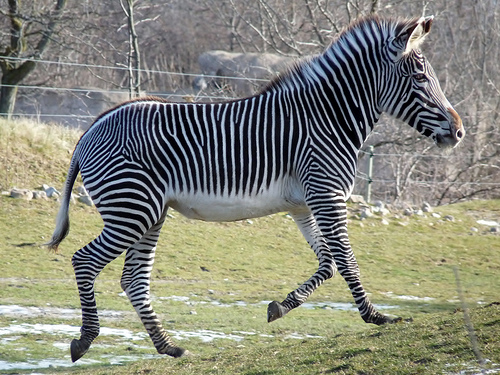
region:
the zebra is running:
[25, 31, 499, 371]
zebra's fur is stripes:
[14, 4, 464, 374]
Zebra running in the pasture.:
[50, 17, 465, 357]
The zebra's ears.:
[400, 15, 435, 53]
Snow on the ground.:
[186, 326, 257, 343]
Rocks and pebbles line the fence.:
[356, 190, 436, 227]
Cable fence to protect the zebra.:
[367, 149, 499, 199]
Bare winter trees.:
[2, 1, 62, 114]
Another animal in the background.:
[199, 49, 284, 89]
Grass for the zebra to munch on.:
[334, 338, 434, 374]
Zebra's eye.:
[411, 68, 432, 85]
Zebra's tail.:
[48, 163, 73, 251]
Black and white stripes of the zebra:
[163, 107, 260, 146]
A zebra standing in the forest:
[23, 0, 473, 372]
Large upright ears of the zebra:
[388, 16, 443, 42]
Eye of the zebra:
[411, 63, 433, 90]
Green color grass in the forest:
[185, 245, 257, 287]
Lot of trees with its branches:
[18, 0, 335, 34]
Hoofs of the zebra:
[64, 341, 202, 361]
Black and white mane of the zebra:
[259, 10, 372, 63]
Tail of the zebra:
[49, 167, 69, 259]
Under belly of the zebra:
[173, 202, 299, 221]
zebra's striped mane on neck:
[270, 18, 394, 85]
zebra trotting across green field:
[41, 11, 468, 361]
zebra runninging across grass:
[40, 10, 467, 362]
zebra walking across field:
[37, 17, 477, 355]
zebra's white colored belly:
[155, 165, 318, 225]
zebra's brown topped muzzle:
[426, 90, 469, 160]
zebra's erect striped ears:
[393, 17, 438, 52]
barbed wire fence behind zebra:
[1, 53, 494, 184]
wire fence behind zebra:
[3, 46, 496, 177]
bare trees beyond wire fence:
[105, 0, 492, 130]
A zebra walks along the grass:
[50, 11, 462, 366]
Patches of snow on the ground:
[1, 294, 388, 371]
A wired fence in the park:
[0, 56, 495, 216]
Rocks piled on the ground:
[5, 181, 95, 209]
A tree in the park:
[1, 2, 68, 119]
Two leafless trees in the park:
[106, 3, 151, 101]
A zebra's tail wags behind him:
[50, 149, 80, 254]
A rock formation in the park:
[1, 49, 318, 135]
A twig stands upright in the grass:
[442, 260, 489, 372]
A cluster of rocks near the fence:
[342, 196, 472, 233]